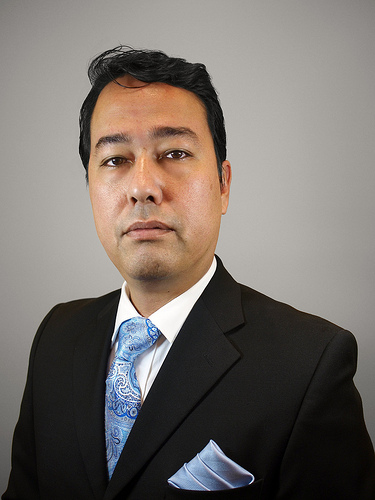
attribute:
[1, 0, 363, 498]
background — gray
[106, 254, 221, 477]
shirt — white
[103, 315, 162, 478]
neck tie — blue, paisley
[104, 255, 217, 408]
shirt — collared, white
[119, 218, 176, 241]
mouth — closed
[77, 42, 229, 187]
hair — short, black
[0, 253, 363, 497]
suit jacket — black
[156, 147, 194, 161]
eye — brown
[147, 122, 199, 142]
eyebrow — black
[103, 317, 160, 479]
tie — blue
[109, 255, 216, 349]
collar — white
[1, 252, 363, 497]
suit — black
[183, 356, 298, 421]
suit — black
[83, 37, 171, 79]
hair — black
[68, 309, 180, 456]
tie — blue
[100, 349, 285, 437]
jacket — black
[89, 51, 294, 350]
man — suit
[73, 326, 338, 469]
jacket — black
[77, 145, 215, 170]
eyes — brown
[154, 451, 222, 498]
pocket square — folded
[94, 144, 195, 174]
eyes —  brown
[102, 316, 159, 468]
tie — blue